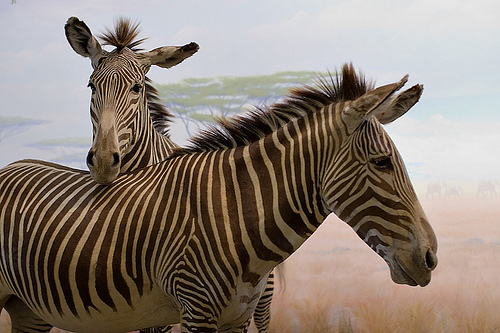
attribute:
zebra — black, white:
[6, 62, 469, 323]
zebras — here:
[7, 17, 442, 324]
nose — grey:
[409, 230, 445, 276]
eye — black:
[366, 152, 397, 173]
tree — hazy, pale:
[153, 68, 319, 127]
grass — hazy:
[291, 268, 443, 333]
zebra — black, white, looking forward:
[51, 6, 199, 192]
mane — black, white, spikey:
[204, 69, 304, 146]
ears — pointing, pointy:
[351, 57, 428, 139]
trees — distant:
[13, 103, 89, 168]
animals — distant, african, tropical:
[422, 162, 496, 227]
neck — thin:
[255, 107, 323, 275]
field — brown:
[309, 209, 494, 329]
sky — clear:
[183, 11, 445, 70]